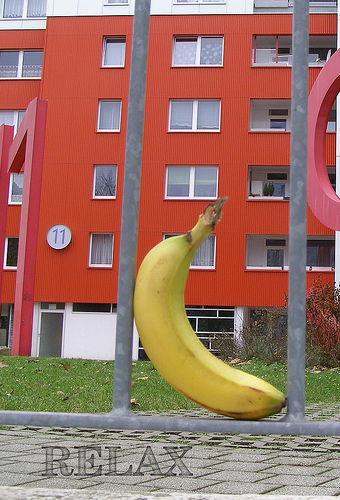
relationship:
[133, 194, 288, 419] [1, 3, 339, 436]
banana on fence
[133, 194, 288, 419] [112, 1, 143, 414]
banana against bar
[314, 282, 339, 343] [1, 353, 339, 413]
leaves on grass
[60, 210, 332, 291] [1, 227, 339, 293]
windows on first floor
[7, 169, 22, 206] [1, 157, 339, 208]
window on second floor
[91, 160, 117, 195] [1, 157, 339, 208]
window on second floor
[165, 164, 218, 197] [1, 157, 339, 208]
window on second floor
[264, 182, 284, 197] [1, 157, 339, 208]
window on second floor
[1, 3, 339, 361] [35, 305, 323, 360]
building has bottom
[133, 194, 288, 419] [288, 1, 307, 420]
banana between bar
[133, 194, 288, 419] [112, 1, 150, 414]
banana between bar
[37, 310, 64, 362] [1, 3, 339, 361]
glass door on building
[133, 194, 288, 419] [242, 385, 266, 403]
banana has bruisies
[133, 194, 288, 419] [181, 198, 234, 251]
banana has stem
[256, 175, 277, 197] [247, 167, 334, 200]
bush on balcony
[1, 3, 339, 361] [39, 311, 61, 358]
building has glass door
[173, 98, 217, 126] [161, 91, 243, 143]
white curtains in window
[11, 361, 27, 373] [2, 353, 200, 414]
leaf on grass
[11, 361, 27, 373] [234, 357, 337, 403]
leaf on grass